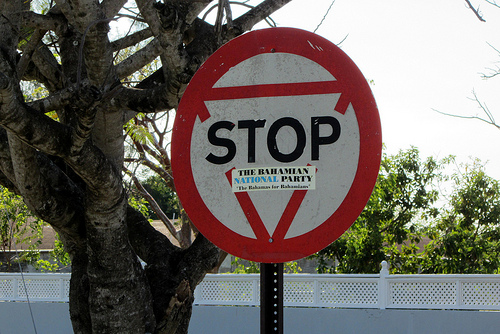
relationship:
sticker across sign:
[230, 165, 319, 194] [164, 25, 390, 268]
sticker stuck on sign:
[230, 165, 319, 194] [164, 25, 390, 268]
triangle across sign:
[195, 82, 360, 239] [164, 25, 390, 268]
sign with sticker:
[164, 25, 390, 268] [230, 165, 319, 194]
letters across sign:
[203, 114, 343, 164] [164, 25, 390, 268]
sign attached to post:
[164, 25, 390, 268] [257, 261, 286, 333]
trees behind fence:
[0, 0, 499, 275] [0, 260, 500, 311]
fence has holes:
[1, 270, 500, 315] [323, 277, 460, 311]